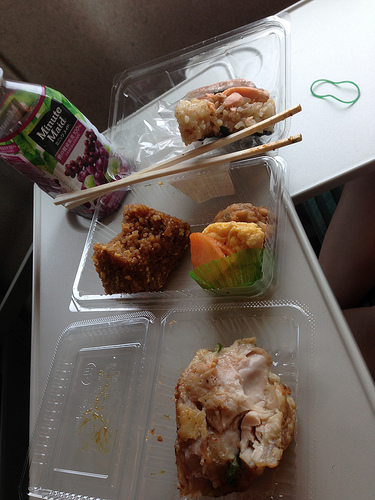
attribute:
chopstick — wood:
[56, 133, 298, 203]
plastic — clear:
[13, 303, 318, 500]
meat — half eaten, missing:
[175, 338, 298, 498]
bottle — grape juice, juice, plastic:
[2, 70, 136, 219]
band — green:
[308, 77, 359, 104]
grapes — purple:
[63, 127, 108, 179]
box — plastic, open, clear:
[68, 12, 295, 298]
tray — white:
[29, 59, 374, 499]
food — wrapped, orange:
[191, 222, 266, 288]